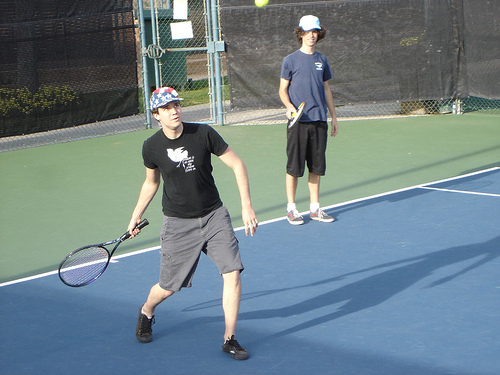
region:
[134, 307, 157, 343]
the black shoe of a man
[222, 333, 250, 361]
the black sneaker of a man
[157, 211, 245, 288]
the grey shorts of a man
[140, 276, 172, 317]
the bare leg of a man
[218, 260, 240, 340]
the bare leg of a man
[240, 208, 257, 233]
the hand of a man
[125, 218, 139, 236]
the hand of a man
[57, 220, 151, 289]
a black tennis racket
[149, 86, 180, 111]
the red white and blue cap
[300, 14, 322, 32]
the white baseball cap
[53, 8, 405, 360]
doubled tennis match on courts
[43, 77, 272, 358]
boy with a black tennis racket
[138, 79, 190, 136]
boy in an American flag hat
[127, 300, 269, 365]
boy wearing shoes without socks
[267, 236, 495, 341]
shadow of a boy on tennis courts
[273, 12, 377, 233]
boy holding a tennis court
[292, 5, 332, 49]
boy with lots of curly hair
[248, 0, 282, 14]
yellow tennis ball in air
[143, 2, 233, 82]
chain link fence with paper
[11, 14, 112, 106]
chain link fence with black cover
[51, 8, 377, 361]
two boys playing tennis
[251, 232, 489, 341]
shadow on the tennis courts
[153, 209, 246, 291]
gray shorts worn by a boy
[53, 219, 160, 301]
black tennis racket being held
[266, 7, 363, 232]
boy with a hat holding a tennis racket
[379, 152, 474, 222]
white lines on a tennis court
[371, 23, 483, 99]
chain link fence covered in black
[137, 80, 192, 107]
patriotic baseball cap on head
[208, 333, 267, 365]
black shoe worn without socks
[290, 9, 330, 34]
white baseball cap on curly haired boy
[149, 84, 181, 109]
america flag theme ball cap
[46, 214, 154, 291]
navy and black tennis racquet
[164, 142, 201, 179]
white print on black shirt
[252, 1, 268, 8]
green tennis ball in air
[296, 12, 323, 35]
white ball cap on man in back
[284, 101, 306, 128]
tennis racquet in man's hand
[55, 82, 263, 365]
man preparing to hit ball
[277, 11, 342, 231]
man observing team mate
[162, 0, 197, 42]
signs posted on court gate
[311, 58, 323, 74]
white print on chest area of blue shirt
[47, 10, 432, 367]
two boys playing tennis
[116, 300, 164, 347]
black shoe on boy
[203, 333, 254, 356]
black shoe on boy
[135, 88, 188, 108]
american flag hat on boy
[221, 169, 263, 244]
left arm of boy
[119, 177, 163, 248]
right arm of boy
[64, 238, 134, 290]
tennis racquet in hand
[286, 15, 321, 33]
white hat on boy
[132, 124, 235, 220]
black tshirt on boy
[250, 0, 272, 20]
tennis ball in air